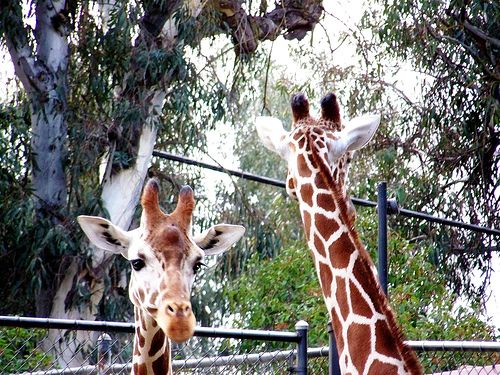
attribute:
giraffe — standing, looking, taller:
[269, 91, 415, 369]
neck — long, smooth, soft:
[317, 220, 420, 366]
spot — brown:
[331, 235, 355, 267]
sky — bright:
[320, 5, 417, 105]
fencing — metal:
[201, 352, 330, 373]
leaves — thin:
[152, 66, 204, 124]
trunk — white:
[107, 41, 174, 195]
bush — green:
[255, 254, 482, 338]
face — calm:
[120, 224, 201, 340]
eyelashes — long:
[195, 259, 209, 268]